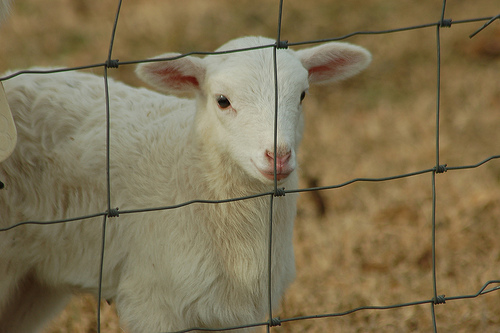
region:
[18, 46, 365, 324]
white lamb behind fence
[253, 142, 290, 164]
pink nose of white lamb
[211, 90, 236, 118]
black eye of white lamb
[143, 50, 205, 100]
pink inside of ear of white lamb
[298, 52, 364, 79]
pink inside of ear of white lamb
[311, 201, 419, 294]
brown grass in enclosure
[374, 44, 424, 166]
brown grass in enclosure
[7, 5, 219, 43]
brown grass in enclosure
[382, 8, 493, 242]
brown grass in enclosure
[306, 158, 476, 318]
brown grass in enclosure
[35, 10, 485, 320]
black wire rectangular shaped fence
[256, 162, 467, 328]
rectangle shaped wire fencing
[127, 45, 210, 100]
white sheep ear with pink inside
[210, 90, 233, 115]
black rounded sheep eye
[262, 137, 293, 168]
pink sheep nose with small nostrils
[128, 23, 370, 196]
white sheep head with ears sticking out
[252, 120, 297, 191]
white sheep snout with pink nose and mouth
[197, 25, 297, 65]
top of white sheep head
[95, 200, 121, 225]
wire joining of fence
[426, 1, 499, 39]
stray piece of wire fencing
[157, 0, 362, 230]
little white sheep head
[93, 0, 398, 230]
sheep looking on from pen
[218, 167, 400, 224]
wired fence to keep sheep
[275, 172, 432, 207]
sheep pen wire for herding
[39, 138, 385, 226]
body and nose of a sheep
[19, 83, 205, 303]
body of a sheep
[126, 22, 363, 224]
white sheep happy face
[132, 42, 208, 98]
baby sheep tiny ear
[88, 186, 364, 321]
fence to keep sheep inside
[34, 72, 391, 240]
baby sheep inside a pen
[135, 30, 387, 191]
the head of a lamb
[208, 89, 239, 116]
the eye of a lamb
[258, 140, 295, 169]
the nose of a lamb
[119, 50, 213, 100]
the ear of a lamb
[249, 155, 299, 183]
the mouth of a lamb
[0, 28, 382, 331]
a white lamb behind the fence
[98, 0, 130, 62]
a wire in the fence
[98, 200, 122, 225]
a joint on the fence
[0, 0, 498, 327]
a metal wire fence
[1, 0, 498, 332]
a yellow field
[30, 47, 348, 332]
the lamb is white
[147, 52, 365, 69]
inside of ears are pink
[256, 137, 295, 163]
the nose is pink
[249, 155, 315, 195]
the mouth is pink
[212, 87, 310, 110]
the eyes are black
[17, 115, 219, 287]
the fur is white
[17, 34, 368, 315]
animal is behind fence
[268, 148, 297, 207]
the fence is made of metal wire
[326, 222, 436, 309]
the ground is brown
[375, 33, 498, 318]
ground is behind fence